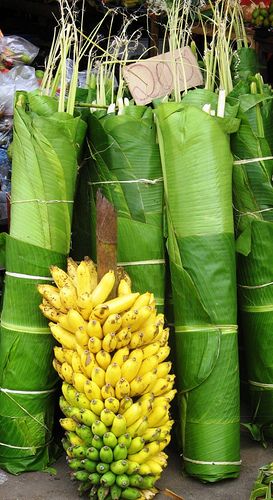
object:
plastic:
[0, 30, 40, 69]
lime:
[15, 42, 35, 64]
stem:
[246, 81, 256, 90]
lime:
[250, 5, 273, 32]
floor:
[0, 447, 273, 499]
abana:
[118, 433, 132, 445]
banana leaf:
[0, 48, 273, 499]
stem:
[96, 185, 118, 298]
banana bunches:
[39, 257, 175, 499]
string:
[84, 176, 162, 188]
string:
[92, 257, 166, 267]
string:
[152, 297, 165, 306]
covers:
[0, 35, 39, 89]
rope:
[192, 458, 227, 465]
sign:
[121, 47, 205, 106]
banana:
[36, 255, 178, 499]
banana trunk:
[37, 191, 179, 499]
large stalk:
[15, 69, 265, 165]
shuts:
[43, 0, 252, 109]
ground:
[0, 455, 273, 500]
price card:
[121, 46, 204, 107]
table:
[153, 17, 256, 55]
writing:
[127, 54, 194, 102]